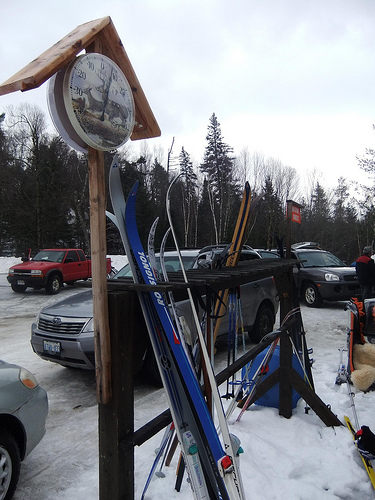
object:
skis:
[105, 155, 301, 499]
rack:
[105, 255, 344, 500]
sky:
[1, 0, 375, 217]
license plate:
[43, 340, 61, 353]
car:
[30, 243, 282, 388]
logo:
[138, 251, 166, 308]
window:
[63, 250, 79, 264]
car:
[7, 249, 112, 294]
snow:
[120, 349, 374, 499]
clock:
[46, 51, 136, 153]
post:
[87, 147, 111, 407]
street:
[2, 271, 110, 481]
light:
[31, 270, 44, 279]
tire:
[47, 274, 62, 295]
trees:
[0, 102, 375, 260]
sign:
[286, 202, 301, 224]